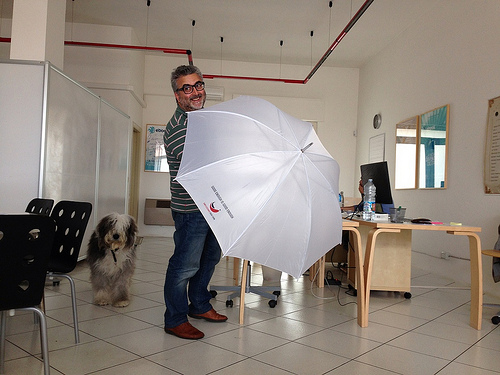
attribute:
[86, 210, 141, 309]
dog — shaggy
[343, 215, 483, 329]
table — wooden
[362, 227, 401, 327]
leg — curved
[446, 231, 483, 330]
leg — curved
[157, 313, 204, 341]
shoe — brown, leather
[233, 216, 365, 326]
wooden table — woode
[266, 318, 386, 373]
floor — tiled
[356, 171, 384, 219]
bottle — plastic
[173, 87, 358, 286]
umbrella — large, big, white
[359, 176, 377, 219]
bottle — fully, water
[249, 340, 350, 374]
tile — white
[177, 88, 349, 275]
umbrella — open, large, opened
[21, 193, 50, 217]
chair — flate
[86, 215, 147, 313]
dog — shaggy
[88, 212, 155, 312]
dog — black, white, furry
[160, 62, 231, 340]
man — standing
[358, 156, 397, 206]
screen — flat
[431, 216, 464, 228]
posted notes — pink, yellow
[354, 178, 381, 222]
bottle — water